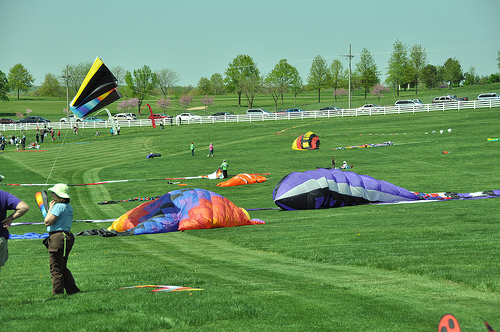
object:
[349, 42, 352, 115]
pole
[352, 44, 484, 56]
wires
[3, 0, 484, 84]
sky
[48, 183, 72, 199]
hat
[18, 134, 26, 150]
people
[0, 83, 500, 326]
grass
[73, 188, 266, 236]
balloon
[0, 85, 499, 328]
ground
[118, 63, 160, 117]
trees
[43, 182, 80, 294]
person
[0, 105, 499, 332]
field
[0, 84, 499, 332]
field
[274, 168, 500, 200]
blue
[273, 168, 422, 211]
balloon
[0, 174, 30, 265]
man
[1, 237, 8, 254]
hip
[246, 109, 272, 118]
car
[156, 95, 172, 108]
bloom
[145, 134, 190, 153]
small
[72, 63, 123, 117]
black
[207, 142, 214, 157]
woman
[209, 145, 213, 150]
shirt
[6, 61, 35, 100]
tree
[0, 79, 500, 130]
distance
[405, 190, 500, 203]
tail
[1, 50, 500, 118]
row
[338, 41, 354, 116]
telephone pole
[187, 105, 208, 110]
road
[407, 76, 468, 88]
house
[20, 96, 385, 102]
line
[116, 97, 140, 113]
trees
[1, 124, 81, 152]
group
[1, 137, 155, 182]
walking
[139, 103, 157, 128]
flight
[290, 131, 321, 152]
kite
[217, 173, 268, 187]
kite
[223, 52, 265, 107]
tree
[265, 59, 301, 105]
tree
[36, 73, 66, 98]
tree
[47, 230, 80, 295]
pants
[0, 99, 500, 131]
fence